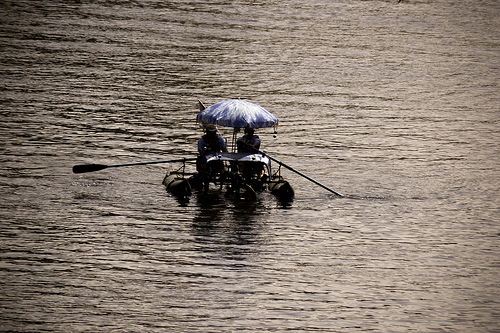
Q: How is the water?
A: Gray with ripples.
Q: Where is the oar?
A: In water.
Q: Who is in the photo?
A: Two people.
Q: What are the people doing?
A: Sailing.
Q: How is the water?
A: Still.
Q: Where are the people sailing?
A: In water.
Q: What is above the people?
A: Umbrella.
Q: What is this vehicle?
A: A boat.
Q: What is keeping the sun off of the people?
A: An umbrella.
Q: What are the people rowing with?
A: Paddles.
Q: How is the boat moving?
A: With paddles.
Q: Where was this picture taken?
A: On the water.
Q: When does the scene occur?
A: Daytime.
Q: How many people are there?
A: Two.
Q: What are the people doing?
A: Paddling a boat.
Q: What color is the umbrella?
A: Blue.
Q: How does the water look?
A: Calm.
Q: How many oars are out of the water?
A: One.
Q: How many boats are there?
A: One.